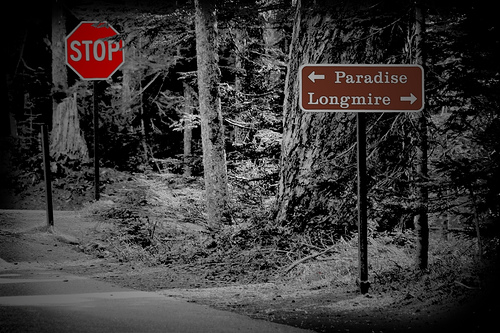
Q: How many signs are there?
A: Two.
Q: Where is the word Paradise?
A: On the brown sign.